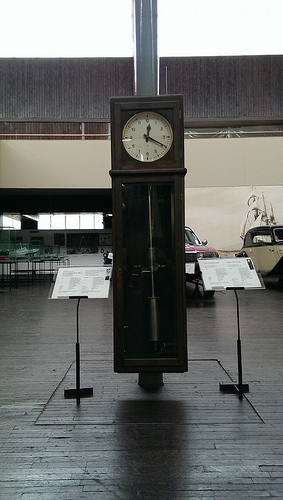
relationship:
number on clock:
[143, 116, 152, 123] [106, 88, 187, 377]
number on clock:
[156, 119, 163, 131] [106, 88, 187, 377]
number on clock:
[166, 126, 169, 135] [106, 88, 187, 377]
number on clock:
[163, 134, 166, 140] [106, 88, 187, 377]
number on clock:
[162, 145, 170, 147] [106, 88, 187, 377]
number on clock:
[135, 121, 143, 122] [106, 88, 187, 377]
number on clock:
[132, 126, 137, 129] [106, 88, 187, 377]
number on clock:
[126, 139, 136, 143] [106, 88, 187, 377]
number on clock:
[130, 146, 135, 150] [106, 88, 187, 377]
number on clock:
[137, 152, 138, 157] [106, 88, 187, 377]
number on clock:
[146, 155, 151, 160] [106, 88, 187, 377]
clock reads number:
[106, 88, 187, 377] [145, 151, 149, 157]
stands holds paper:
[196, 248, 263, 400] [198, 255, 257, 293]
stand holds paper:
[53, 259, 113, 403] [51, 262, 108, 301]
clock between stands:
[106, 88, 187, 377] [57, 253, 249, 399]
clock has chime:
[106, 88, 187, 377] [143, 181, 162, 348]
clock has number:
[106, 88, 187, 377] [145, 151, 149, 157]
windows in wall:
[1, 199, 106, 233] [14, 60, 282, 254]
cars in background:
[103, 221, 282, 285] [14, 60, 282, 254]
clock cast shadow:
[106, 88, 187, 377] [102, 392, 199, 499]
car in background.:
[103, 225, 221, 274] [3, 57, 281, 300]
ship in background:
[239, 190, 276, 231] [3, 57, 281, 300]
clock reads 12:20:
[106, 88, 187, 377] [142, 120, 169, 149]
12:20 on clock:
[142, 120, 169, 149] [106, 88, 187, 377]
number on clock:
[145, 151, 149, 157] [106, 88, 187, 377]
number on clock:
[155, 150, 159, 156] [106, 88, 187, 377]